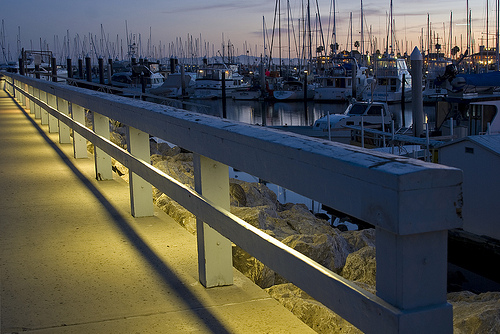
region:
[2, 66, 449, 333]
The guard rail is thick.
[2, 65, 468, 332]
The guard rail is white.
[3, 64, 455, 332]
The guardrail is made of wood.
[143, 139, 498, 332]
Rocks are behind the guardrail.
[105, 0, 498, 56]
The sky is blue and pink.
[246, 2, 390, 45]
The sky has clouds in it.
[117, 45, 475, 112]
A lot of boats are in the picture.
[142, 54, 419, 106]
The boats are mostly white.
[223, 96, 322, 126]
The water is reflecting light.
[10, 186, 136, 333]
The sidewalk is gray.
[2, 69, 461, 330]
the railing along the walkway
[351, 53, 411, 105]
boat in the bay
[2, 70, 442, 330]
lighting along the walkway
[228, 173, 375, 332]
rocks to retain the water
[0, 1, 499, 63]
an array of masts of boats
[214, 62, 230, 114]
posts in the bay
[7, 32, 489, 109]
boats in a marina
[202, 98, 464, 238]
wooden hand rail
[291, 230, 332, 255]
green growth on the rocks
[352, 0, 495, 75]
sun either rising or setting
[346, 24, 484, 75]
A sky at sunset.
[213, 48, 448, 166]
A boat harbor.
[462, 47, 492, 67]
Yellow and red lights glowing in the distance.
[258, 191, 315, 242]
Rocks surrounding structure.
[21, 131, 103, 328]
A cement walkway.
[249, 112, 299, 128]
Boats reflecting in the water.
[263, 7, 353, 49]
Purple and blue clouds.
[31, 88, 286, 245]
A wooden guard rail.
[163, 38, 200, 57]
Boat's sail mast.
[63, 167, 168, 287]
Bright yellow light on the cement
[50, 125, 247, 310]
a lit up railing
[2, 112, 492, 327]
wooden railing by the dock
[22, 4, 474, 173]
a harbor for sailboats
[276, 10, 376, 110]
a sailboat in the water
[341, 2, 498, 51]
an orange sunset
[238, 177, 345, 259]
rocks by the water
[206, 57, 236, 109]
a wooden pole in the water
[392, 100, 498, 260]
a house on the marina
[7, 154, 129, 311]
the sidewalk of the dock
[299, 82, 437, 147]
a boat in the water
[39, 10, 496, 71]
multiple ship flag poles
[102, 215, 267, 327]
glowing light on the concrete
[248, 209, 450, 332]
numerous gray rocks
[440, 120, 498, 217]
a small white building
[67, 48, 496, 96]
several boats in a marina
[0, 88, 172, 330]
a concrete walkway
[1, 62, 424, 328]
a long white railing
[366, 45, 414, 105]
a double decker fishing boat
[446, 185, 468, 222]
chipped paint at the end of a railing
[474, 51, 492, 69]
bright lights from a boat's interior